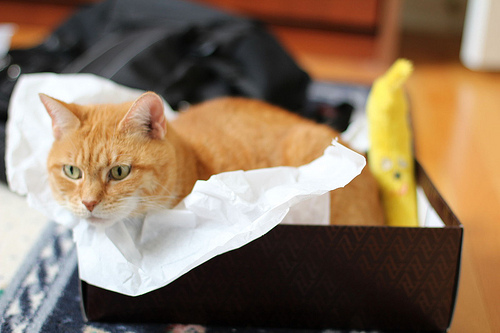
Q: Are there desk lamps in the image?
A: No, there are no desk lamps.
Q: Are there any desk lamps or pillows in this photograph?
A: No, there are no desk lamps or pillows.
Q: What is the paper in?
A: The paper is in the box.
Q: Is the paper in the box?
A: Yes, the paper is in the box.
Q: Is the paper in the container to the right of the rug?
A: Yes, the paper is in the box.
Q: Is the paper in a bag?
A: No, the paper is in the box.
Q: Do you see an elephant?
A: No, there are no elephants.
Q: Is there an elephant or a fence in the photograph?
A: No, there are no elephants or fences.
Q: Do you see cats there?
A: Yes, there is a cat.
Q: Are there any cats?
A: Yes, there is a cat.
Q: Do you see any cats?
A: Yes, there is a cat.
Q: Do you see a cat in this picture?
A: Yes, there is a cat.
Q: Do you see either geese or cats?
A: Yes, there is a cat.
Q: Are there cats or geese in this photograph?
A: Yes, there is a cat.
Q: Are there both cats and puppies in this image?
A: No, there is a cat but no puppies.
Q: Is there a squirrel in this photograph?
A: No, there are no squirrels.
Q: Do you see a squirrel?
A: No, there are no squirrels.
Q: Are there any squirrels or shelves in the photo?
A: No, there are no squirrels or shelves.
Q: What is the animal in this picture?
A: The animal is a cat.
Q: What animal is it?
A: The animal is a cat.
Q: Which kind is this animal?
A: That is a cat.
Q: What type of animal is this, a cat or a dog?
A: That is a cat.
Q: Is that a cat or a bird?
A: That is a cat.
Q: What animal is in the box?
A: The animal is a cat.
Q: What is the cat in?
A: The cat is in the box.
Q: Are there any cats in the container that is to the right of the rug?
A: Yes, there is a cat in the box.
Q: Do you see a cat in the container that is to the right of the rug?
A: Yes, there is a cat in the box.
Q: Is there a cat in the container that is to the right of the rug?
A: Yes, there is a cat in the box.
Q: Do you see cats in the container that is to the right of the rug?
A: Yes, there is a cat in the box.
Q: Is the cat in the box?
A: Yes, the cat is in the box.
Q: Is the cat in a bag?
A: No, the cat is in the box.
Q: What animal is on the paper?
A: The cat is on the paper.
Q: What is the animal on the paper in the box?
A: The animal is a cat.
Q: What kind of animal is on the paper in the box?
A: The animal is a cat.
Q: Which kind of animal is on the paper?
A: The animal is a cat.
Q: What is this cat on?
A: The cat is on the paper.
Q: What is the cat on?
A: The cat is on the paper.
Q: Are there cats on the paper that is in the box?
A: Yes, there is a cat on the paper.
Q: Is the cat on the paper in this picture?
A: Yes, the cat is on the paper.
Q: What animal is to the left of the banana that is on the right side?
A: The animal is a cat.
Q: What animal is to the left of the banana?
A: The animal is a cat.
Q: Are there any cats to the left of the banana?
A: Yes, there is a cat to the left of the banana.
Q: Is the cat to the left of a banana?
A: Yes, the cat is to the left of a banana.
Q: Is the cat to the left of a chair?
A: No, the cat is to the left of a banana.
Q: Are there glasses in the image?
A: No, there are no glasses.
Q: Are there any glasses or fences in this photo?
A: No, there are no glasses or fences.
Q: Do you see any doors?
A: Yes, there is a door.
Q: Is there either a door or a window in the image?
A: Yes, there is a door.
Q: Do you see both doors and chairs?
A: No, there is a door but no chairs.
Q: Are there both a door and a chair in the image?
A: No, there is a door but no chairs.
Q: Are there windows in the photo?
A: No, there are no windows.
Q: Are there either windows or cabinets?
A: No, there are no windows or cabinets.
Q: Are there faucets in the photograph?
A: No, there are no faucets.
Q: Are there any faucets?
A: No, there are no faucets.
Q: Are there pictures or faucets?
A: No, there are no faucets or pictures.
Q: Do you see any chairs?
A: No, there are no chairs.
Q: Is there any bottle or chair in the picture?
A: No, there are no chairs or bottles.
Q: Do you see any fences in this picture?
A: No, there are no fences.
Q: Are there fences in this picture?
A: No, there are no fences.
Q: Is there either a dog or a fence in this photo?
A: No, there are no fences or dogs.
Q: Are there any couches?
A: No, there are no couches.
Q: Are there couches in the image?
A: No, there are no couches.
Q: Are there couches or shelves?
A: No, there are no couches or shelves.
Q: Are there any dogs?
A: No, there are no dogs.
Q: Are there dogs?
A: No, there are no dogs.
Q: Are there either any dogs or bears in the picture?
A: No, there are no dogs or bears.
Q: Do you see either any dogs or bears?
A: No, there are no dogs or bears.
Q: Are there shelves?
A: No, there are no shelves.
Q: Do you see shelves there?
A: No, there are no shelves.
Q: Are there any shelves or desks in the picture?
A: No, there are no shelves or desks.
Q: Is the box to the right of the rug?
A: Yes, the box is to the right of the rug.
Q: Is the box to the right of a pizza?
A: No, the box is to the right of the rug.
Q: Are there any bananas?
A: Yes, there is a banana.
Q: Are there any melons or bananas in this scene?
A: Yes, there is a banana.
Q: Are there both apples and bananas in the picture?
A: No, there is a banana but no apples.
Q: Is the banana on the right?
A: Yes, the banana is on the right of the image.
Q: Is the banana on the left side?
A: No, the banana is on the right of the image.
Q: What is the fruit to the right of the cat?
A: The fruit is a banana.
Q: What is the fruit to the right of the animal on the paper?
A: The fruit is a banana.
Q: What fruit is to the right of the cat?
A: The fruit is a banana.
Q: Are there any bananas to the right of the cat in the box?
A: Yes, there is a banana to the right of the cat.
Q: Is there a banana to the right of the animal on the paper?
A: Yes, there is a banana to the right of the cat.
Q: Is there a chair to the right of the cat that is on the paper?
A: No, there is a banana to the right of the cat.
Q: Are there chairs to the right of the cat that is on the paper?
A: No, there is a banana to the right of the cat.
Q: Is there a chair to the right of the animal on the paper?
A: No, there is a banana to the right of the cat.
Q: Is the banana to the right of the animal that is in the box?
A: Yes, the banana is to the right of the cat.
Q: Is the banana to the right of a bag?
A: No, the banana is to the right of the cat.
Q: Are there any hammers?
A: No, there are no hammers.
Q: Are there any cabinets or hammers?
A: No, there are no hammers or cabinets.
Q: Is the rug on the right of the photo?
A: No, the rug is on the left of the image.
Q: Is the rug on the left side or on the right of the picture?
A: The rug is on the left of the image.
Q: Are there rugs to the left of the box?
A: Yes, there is a rug to the left of the box.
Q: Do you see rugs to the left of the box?
A: Yes, there is a rug to the left of the box.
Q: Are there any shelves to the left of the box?
A: No, there is a rug to the left of the box.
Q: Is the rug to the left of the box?
A: Yes, the rug is to the left of the box.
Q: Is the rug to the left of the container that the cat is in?
A: Yes, the rug is to the left of the box.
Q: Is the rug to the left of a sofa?
A: No, the rug is to the left of the box.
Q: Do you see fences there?
A: No, there are no fences.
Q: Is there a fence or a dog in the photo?
A: No, there are no fences or dogs.